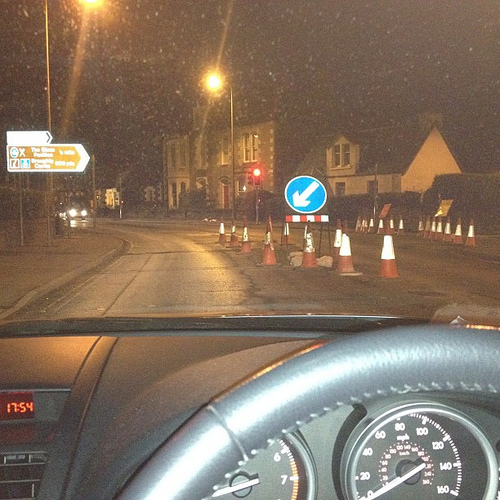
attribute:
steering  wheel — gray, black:
[303, 330, 482, 390]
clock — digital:
[2, 390, 36, 419]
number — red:
[6, 403, 12, 415]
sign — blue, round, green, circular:
[281, 170, 331, 212]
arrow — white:
[291, 192, 318, 208]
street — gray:
[124, 216, 491, 318]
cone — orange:
[442, 96, 451, 247]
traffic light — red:
[249, 166, 271, 183]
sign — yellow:
[6, 144, 93, 171]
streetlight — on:
[200, 65, 227, 96]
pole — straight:
[225, 88, 239, 222]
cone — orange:
[435, 219, 445, 244]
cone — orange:
[385, 216, 397, 233]